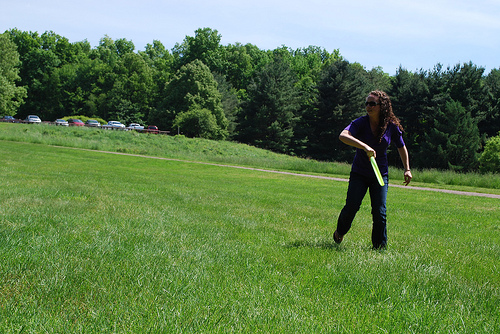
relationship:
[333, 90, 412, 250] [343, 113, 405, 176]
woman wearing purple shirt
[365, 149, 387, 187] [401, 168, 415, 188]
frisbee in hand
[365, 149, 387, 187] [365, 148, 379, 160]
frisbee in hand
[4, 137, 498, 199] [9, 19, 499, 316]
path going through field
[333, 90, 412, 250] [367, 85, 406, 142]
woman has hair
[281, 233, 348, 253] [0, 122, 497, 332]
shadow in grass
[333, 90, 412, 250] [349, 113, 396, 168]
woman wearing purple shirt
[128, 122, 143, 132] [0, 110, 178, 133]
car in field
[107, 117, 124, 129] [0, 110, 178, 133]
car in field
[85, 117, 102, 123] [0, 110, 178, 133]
car in field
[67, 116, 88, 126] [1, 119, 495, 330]
car in field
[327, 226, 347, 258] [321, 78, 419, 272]
sandals on woman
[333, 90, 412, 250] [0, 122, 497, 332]
woman standing in grass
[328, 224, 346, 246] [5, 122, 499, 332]
foot lifted off ground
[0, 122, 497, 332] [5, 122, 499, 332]
grass on ground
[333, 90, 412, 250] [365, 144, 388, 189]
woman throwing frisbee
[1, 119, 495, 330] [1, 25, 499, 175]
field of trees